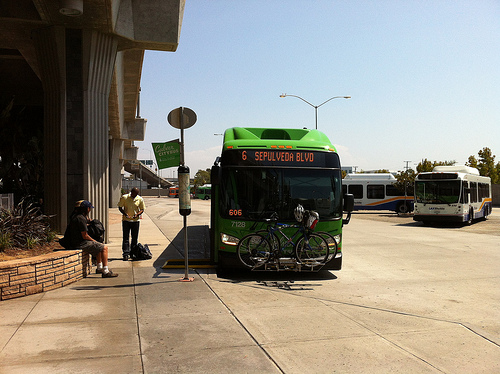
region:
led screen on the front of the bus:
[238, 143, 319, 163]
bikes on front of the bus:
[246, 206, 341, 284]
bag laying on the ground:
[126, 234, 148, 259]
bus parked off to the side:
[388, 141, 493, 235]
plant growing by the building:
[8, 191, 55, 250]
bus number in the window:
[224, 204, 243, 216]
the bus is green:
[213, 118, 348, 268]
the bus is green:
[180, 100, 366, 289]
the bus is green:
[185, 91, 370, 331]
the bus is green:
[197, 89, 349, 319]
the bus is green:
[182, 99, 382, 332]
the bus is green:
[179, 84, 369, 317]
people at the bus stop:
[52, 162, 182, 291]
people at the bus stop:
[67, 179, 171, 302]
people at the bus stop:
[66, 168, 176, 293]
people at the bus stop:
[40, 153, 169, 289]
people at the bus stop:
[57, 168, 171, 270]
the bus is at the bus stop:
[214, 127, 346, 275]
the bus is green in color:
[217, 124, 349, 274]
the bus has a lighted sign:
[243, 148, 323, 164]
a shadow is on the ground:
[159, 223, 334, 281]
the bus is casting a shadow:
[163, 123, 347, 289]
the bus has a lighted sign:
[239, 148, 324, 165]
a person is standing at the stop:
[117, 187, 147, 257]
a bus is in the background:
[404, 168, 492, 228]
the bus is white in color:
[412, 163, 493, 224]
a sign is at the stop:
[161, 106, 198, 271]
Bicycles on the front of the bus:
[238, 204, 337, 270]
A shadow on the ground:
[152, 224, 212, 274]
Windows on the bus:
[219, 165, 339, 218]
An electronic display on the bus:
[238, 149, 318, 163]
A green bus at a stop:
[213, 128, 353, 273]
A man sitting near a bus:
[66, 198, 118, 275]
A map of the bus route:
[177, 164, 192, 214]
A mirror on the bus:
[342, 192, 356, 224]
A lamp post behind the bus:
[280, 91, 351, 129]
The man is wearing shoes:
[95, 265, 115, 277]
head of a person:
[120, 184, 145, 201]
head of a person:
[72, 204, 99, 220]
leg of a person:
[94, 243, 115, 276]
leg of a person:
[117, 220, 129, 257]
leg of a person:
[128, 225, 150, 253]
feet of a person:
[106, 274, 123, 282]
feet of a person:
[90, 259, 107, 277]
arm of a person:
[110, 188, 127, 210]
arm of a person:
[130, 199, 146, 216]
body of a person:
[119, 190, 149, 216]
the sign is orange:
[242, 139, 329, 177]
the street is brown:
[145, 291, 246, 343]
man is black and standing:
[113, 183, 158, 244]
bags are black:
[120, 233, 160, 271]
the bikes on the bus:
[238, 206, 333, 277]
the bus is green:
[220, 126, 345, 273]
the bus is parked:
[406, 163, 493, 239]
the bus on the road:
[407, 162, 487, 245]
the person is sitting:
[78, 190, 114, 285]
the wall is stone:
[28, 248, 78, 298]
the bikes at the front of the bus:
[212, 126, 353, 272]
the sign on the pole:
[168, 107, 198, 282]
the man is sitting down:
[63, 200, 120, 277]